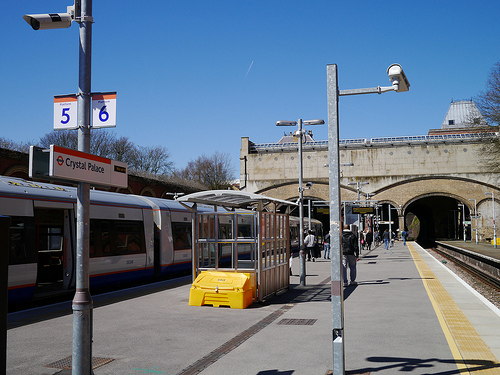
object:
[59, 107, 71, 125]
number 5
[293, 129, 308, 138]
camera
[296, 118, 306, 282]
pole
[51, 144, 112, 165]
stripe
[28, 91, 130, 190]
sign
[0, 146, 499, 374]
station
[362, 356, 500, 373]
shadow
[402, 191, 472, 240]
tunnel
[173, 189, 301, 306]
shelter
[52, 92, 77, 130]
platform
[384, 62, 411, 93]
security camera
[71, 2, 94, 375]
pole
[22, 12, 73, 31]
security camera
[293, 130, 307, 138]
security camera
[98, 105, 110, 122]
blue number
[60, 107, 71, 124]
blue number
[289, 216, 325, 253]
car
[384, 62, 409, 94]
light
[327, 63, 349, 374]
pole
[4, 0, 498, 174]
sky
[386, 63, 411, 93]
camera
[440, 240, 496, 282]
tracks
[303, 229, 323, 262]
person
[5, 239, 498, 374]
ground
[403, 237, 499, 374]
line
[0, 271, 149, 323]
tracks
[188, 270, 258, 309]
yellow box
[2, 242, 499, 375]
concrete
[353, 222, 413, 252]
people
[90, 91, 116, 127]
background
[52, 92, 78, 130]
background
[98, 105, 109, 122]
6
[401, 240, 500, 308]
train track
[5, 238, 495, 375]
platform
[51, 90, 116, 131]
platform number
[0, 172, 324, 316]
train